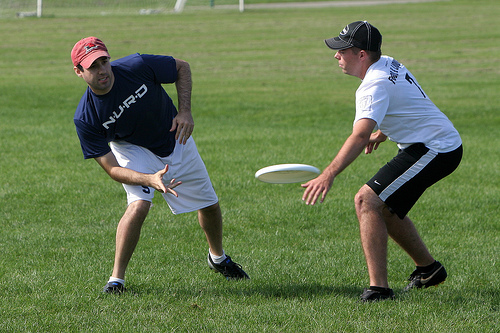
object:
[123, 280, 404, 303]
shadow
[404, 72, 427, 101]
number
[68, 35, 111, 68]
hat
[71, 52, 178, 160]
shirt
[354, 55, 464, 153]
shirt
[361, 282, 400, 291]
jeans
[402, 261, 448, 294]
shoes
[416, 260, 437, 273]
socks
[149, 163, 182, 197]
hand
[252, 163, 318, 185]
frisbee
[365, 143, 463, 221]
shorts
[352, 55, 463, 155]
white shirt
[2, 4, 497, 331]
grass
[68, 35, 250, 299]
man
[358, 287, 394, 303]
shoes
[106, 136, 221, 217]
white shorts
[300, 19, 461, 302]
man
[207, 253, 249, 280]
shoe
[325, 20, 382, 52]
baseball hat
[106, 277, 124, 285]
socks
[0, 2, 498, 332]
field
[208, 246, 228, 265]
sock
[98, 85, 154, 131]
letters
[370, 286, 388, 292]
socks